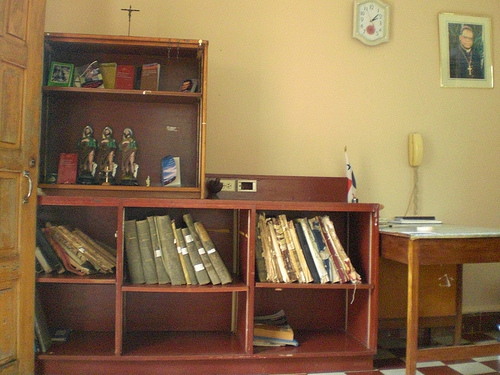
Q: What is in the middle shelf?
A: Books.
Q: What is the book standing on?
A: Shelf.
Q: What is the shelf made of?
A: Wood.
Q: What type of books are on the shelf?
A: Old.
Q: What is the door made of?
A: Wooden.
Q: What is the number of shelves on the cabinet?
A: Two.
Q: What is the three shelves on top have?
A: Books.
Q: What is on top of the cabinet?
A: Cross.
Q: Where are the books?
A: On the shelves.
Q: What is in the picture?
A: A priest.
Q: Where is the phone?
A: On the wall.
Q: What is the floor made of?
A: Tile.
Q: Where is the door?
A: By the book shelf.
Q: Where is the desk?
A: By the book shelf.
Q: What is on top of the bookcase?
A: Cross.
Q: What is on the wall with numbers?
A: Clock.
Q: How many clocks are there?
A: One.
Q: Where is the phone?
A: On the wall.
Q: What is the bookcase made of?
A: Wood.